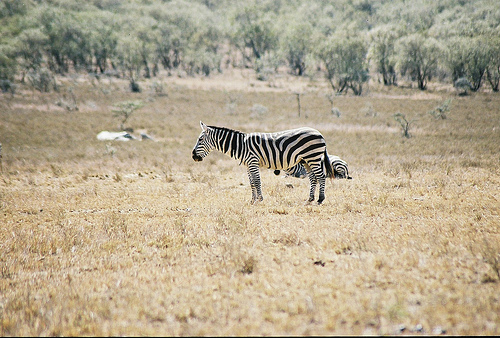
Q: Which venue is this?
A: This is a field.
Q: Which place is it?
A: It is a field.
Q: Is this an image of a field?
A: Yes, it is showing a field.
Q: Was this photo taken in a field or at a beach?
A: It was taken at a field.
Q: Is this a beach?
A: No, it is a field.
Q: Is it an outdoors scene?
A: Yes, it is outdoors.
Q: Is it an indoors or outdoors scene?
A: It is outdoors.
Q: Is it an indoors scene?
A: No, it is outdoors.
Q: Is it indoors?
A: No, it is outdoors.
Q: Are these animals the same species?
A: Yes, all the animals are zebras.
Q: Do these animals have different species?
A: No, all the animals are zebras.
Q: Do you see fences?
A: No, there are no fences.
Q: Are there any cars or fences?
A: No, there are no fences or cars.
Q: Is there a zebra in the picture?
A: Yes, there is a zebra.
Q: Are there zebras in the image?
A: Yes, there is a zebra.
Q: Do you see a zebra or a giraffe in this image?
A: Yes, there is a zebra.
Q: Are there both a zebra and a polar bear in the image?
A: No, there is a zebra but no polar bears.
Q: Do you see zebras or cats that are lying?
A: Yes, the zebra is lying.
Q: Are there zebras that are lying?
A: Yes, there is a zebra that is lying.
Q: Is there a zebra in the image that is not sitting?
A: Yes, there is a zebra that is lying.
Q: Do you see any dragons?
A: No, there are no dragons.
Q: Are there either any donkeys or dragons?
A: No, there are no dragons or donkeys.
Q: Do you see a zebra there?
A: Yes, there is a zebra.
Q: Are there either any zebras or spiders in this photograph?
A: Yes, there is a zebra.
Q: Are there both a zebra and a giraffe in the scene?
A: No, there is a zebra but no giraffes.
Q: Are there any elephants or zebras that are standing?
A: Yes, the zebra is standing.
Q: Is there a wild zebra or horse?
A: Yes, there is a wild zebra.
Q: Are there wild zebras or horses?
A: Yes, there is a wild zebra.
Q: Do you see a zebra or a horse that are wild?
A: Yes, the zebra is wild.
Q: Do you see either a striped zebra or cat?
A: Yes, there is a striped zebra.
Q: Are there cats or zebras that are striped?
A: Yes, the zebra is striped.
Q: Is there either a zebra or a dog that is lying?
A: Yes, the zebra is lying.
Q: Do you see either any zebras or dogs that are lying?
A: Yes, the zebra is lying.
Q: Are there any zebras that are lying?
A: Yes, there is a zebra that is lying.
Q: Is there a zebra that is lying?
A: Yes, there is a zebra that is lying.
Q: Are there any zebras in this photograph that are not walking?
A: Yes, there is a zebra that is lying.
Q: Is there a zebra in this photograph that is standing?
A: Yes, there is a zebra that is standing.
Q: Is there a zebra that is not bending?
A: Yes, there is a zebra that is standing.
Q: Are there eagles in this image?
A: No, there are no eagles.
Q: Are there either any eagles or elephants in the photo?
A: No, there are no eagles or elephants.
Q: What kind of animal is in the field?
A: The animal is a zebra.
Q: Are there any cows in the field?
A: No, there is a zebra in the field.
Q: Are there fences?
A: No, there are no fences.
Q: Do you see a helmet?
A: No, there are no helmets.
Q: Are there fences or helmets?
A: No, there are no helmets or fences.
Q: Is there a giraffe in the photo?
A: No, there are no giraffes.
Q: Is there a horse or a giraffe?
A: No, there are no giraffes or horses.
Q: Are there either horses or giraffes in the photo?
A: No, there are no giraffes or horses.